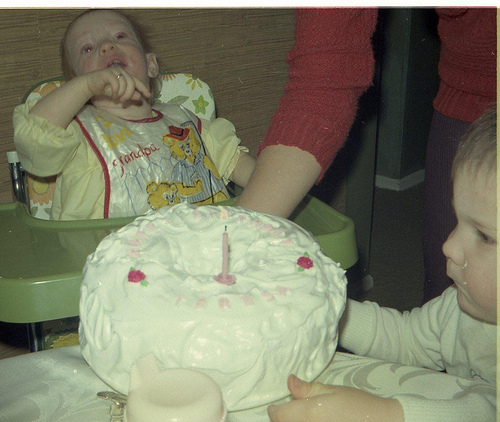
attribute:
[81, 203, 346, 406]
icing — white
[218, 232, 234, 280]
candle — pink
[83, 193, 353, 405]
cake — white, birthday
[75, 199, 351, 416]
cake — birthday, white, frosted, beautiful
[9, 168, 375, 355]
tray — green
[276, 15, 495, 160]
shirt — red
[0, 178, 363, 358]
chair — high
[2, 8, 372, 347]
high chair — green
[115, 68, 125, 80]
ring — gold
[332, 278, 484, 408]
sweatshirt — white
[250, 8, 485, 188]
sweater — red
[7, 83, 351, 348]
chair — high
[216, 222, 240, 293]
candle — pink